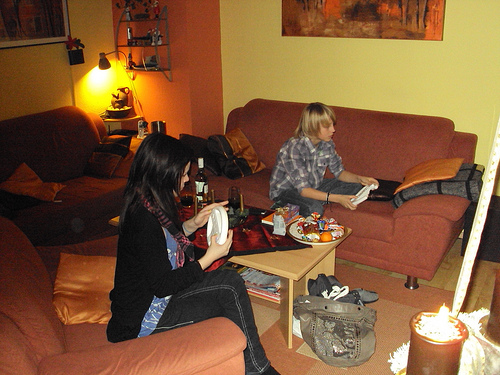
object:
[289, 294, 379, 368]
bag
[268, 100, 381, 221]
boy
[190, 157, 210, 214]
bottle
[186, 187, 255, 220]
teapoy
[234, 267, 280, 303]
magazines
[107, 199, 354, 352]
table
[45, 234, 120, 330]
pillow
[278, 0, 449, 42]
picture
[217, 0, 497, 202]
wall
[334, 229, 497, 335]
ground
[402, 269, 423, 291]
leg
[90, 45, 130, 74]
lamp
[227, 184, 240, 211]
glass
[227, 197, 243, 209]
liquid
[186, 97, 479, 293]
sofa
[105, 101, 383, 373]
children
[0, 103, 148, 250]
couch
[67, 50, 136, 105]
light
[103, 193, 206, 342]
sweater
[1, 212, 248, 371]
chair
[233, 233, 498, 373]
floor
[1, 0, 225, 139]
wall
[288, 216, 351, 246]
plate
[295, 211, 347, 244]
food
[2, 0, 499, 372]
living room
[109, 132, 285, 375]
child